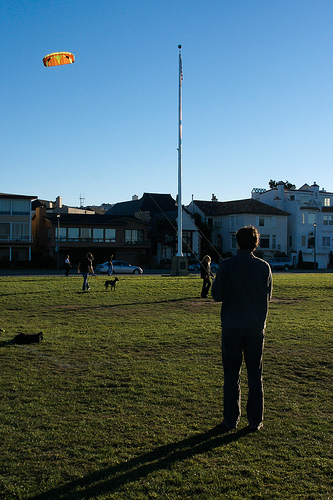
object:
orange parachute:
[41, 47, 77, 71]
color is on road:
[5, 265, 172, 276]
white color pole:
[176, 42, 182, 255]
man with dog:
[75, 251, 120, 294]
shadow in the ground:
[34, 423, 260, 499]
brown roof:
[194, 197, 291, 217]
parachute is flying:
[39, 46, 79, 74]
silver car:
[94, 257, 144, 275]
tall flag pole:
[174, 44, 184, 256]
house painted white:
[255, 180, 333, 268]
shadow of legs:
[39, 417, 260, 499]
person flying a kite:
[199, 253, 215, 299]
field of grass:
[0, 273, 333, 498]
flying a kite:
[41, 50, 75, 72]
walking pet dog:
[77, 250, 121, 293]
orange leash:
[94, 273, 104, 285]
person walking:
[106, 250, 117, 276]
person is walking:
[61, 252, 73, 277]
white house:
[187, 192, 293, 269]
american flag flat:
[178, 48, 184, 101]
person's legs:
[221, 341, 243, 433]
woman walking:
[77, 251, 96, 292]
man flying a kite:
[38, 47, 213, 304]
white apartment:
[186, 198, 291, 260]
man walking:
[62, 250, 74, 278]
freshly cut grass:
[0, 275, 333, 500]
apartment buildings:
[188, 192, 290, 274]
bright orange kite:
[38, 47, 78, 68]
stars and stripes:
[34, 46, 78, 78]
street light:
[312, 223, 319, 272]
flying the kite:
[40, 42, 78, 75]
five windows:
[56, 227, 68, 243]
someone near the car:
[107, 254, 114, 277]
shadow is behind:
[27, 426, 261, 500]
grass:
[0, 270, 332, 500]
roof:
[190, 198, 291, 220]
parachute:
[41, 46, 76, 72]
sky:
[0, 0, 333, 191]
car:
[96, 258, 145, 274]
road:
[27, 263, 173, 277]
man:
[77, 251, 95, 292]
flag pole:
[177, 43, 183, 253]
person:
[212, 225, 273, 427]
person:
[76, 249, 97, 292]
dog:
[104, 276, 120, 292]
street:
[2, 268, 170, 276]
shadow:
[31, 426, 250, 499]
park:
[0, 274, 333, 498]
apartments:
[250, 176, 332, 274]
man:
[209, 223, 274, 438]